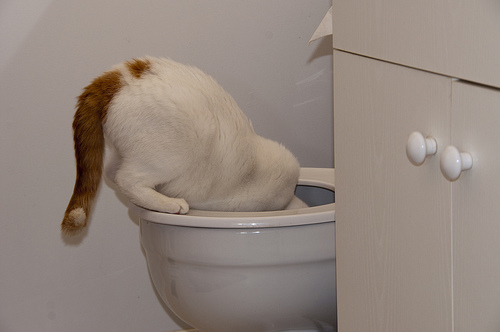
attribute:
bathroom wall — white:
[1, 2, 330, 330]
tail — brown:
[62, 71, 122, 234]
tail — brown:
[55, 64, 124, 244]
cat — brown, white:
[52, 40, 312, 258]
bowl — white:
[121, 155, 348, 330]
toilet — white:
[123, 166, 333, 329]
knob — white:
[437, 146, 474, 181]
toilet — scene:
[120, 153, 308, 330]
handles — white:
[402, 126, 472, 185]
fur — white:
[18, 42, 349, 307]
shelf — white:
[316, 1, 498, 330]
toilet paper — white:
[308, 5, 332, 42]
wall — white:
[3, 4, 333, 330]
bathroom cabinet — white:
[332, 0, 498, 331]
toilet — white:
[138, 164, 339, 328]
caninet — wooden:
[347, 15, 497, 301]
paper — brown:
[302, 3, 337, 45]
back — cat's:
[117, 51, 237, 92]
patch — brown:
[125, 47, 150, 79]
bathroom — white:
[4, 9, 482, 306]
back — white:
[120, 44, 275, 130]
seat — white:
[128, 180, 375, 228]